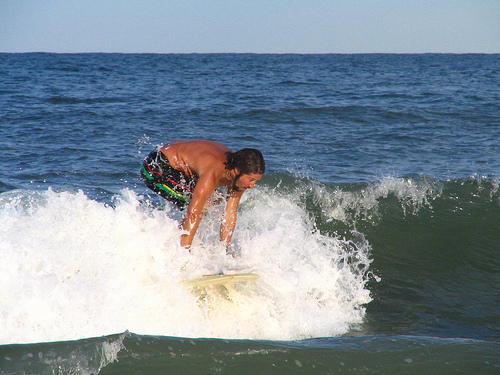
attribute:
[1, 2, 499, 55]
sky — clear, blue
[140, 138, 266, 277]
man — surfing, hunched, standing, half-naked, bent over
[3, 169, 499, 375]
wave — white, crashing, nice, beautiful, attractive, strong, foamy, forming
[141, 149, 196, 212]
trunks — black, red, yellow, green, swim trunks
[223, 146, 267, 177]
hair — brown, long, dark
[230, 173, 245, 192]
beard — brown, long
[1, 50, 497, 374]
ocean — blue, unsettled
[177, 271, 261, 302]
surfboard — white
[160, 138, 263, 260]
skin — tanned, dark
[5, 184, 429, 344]
water — raised, white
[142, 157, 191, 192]
stripe — red